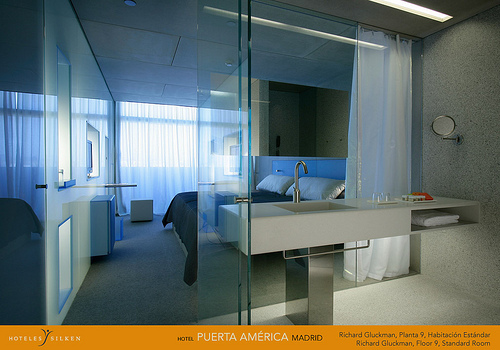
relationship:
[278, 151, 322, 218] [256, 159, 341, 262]
chrome bathroom faucet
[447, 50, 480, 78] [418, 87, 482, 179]
wall mounted mirror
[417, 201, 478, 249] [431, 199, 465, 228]
white folded towels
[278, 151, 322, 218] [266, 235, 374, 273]
chrome towel bar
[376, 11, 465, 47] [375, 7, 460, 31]
overhead fluorescent light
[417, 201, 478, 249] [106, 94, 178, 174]
white window curtains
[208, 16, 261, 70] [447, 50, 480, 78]
glass dividing wall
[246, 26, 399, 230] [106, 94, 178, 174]
opened privacy curtains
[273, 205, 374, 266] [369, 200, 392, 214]
bathroom vanity countertop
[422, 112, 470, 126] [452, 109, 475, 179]
small mirror on the wall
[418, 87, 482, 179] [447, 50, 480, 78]
mirror on wall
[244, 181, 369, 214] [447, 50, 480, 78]
white  sink across wall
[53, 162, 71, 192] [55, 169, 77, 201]
plastic cups on shelf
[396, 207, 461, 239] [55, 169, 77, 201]
towel in shelf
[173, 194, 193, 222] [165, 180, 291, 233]
black quilt blanket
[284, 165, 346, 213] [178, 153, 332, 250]
white pillows on bed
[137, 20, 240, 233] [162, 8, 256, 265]
open glass door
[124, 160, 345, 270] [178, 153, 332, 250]
nicely made bed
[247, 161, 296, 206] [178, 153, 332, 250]
pillows on a bed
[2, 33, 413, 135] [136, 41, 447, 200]
glass wall between bedroom and bathroo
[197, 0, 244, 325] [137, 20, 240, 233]
door propped open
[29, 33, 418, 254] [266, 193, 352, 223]
modern square sink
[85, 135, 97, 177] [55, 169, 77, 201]
television builtin shelf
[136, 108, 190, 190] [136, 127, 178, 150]
window with curtain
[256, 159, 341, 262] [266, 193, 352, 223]
faucet on sink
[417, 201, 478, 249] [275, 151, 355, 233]
white sink area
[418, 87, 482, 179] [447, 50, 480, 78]
mirror attached to wall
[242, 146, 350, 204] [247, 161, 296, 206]
two white pillows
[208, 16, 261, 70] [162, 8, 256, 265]
glass see through door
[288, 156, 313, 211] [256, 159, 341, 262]
long silver faucet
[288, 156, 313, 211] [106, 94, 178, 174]
long white curtains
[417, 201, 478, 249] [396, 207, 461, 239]
white bath towel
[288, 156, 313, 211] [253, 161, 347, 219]
long bed pillow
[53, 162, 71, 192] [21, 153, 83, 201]
clear plastic cup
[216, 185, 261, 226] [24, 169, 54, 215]
silver door handle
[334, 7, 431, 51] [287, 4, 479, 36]
part of a ceiling light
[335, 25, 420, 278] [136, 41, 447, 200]
curtain between bedroom and bathroo